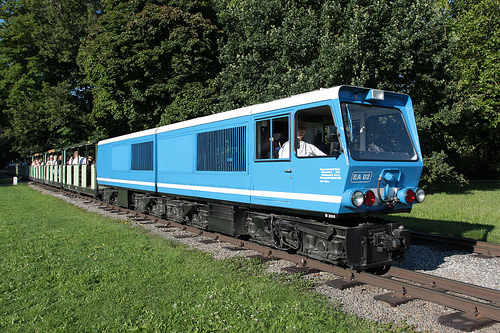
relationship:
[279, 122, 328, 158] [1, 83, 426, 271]
man driving train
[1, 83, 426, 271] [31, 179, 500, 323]
train on tracks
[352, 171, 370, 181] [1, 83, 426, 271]
numbers on train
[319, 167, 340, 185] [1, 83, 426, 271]
lettering on train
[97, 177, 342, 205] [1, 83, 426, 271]
stripe on train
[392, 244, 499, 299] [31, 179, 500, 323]
gravel in tracks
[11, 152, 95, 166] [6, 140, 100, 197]
people in cars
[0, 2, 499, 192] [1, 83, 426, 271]
trees behind train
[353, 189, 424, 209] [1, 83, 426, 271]
headlights on train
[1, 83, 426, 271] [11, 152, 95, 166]
train carrying people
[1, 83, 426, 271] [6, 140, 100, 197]
train pulling cars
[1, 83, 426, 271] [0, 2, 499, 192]
train passing trees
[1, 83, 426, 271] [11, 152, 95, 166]
train with people